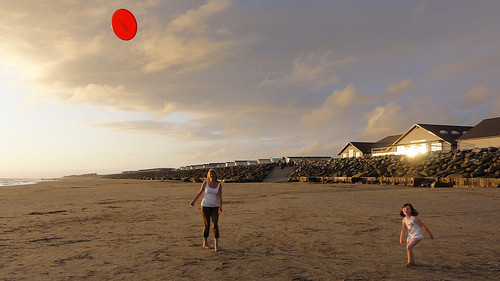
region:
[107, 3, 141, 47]
red plastic frisbee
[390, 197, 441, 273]
little girl wearing white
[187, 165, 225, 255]
woman in a white tank top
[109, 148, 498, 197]
barrier of large grey stones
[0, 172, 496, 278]
light brown sandy beach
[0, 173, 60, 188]
small section of shore line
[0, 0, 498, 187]
cloudy white and blue sky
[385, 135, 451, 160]
yellow sun reflecting off windows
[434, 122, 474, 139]
three sky light windows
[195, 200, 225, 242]
brown capri pants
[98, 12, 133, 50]
red Frisbee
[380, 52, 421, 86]
white clouds in blue sky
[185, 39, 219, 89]
white clouds in blue sky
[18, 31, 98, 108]
white clouds in blue sky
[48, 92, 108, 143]
white clouds in blue sky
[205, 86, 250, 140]
white clouds in blue sky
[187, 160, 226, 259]
lady standing in the sand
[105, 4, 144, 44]
red frisbee in the sky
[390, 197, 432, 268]
girl standing in the sand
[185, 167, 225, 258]
lady wearing a white tank top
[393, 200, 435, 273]
girl wearing a white tank top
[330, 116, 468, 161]
house behind a rock slope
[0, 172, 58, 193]
a small slice of the ocean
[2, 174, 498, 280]
beach is covered in sand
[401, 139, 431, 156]
light reflecting off the window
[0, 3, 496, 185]
sky is blue with clouds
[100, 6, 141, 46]
red Frisbee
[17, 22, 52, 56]
white clouds in blue sky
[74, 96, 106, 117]
white clouds in blue sky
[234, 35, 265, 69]
white clouds in blue sky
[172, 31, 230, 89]
white clouds in blue sky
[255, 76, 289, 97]
white clouds in blue sky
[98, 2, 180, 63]
Frisbee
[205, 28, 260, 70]
white clouds in blue sky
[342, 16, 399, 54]
white clouds in blue sky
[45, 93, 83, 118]
white clouds in blue sky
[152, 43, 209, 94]
white clouds in blue sky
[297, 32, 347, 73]
white clouds in blue sky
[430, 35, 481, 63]
white clouds in blue sky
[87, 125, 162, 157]
white clouds in blue sky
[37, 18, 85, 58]
white clouds in blue sky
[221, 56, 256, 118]
white clouds in blue sky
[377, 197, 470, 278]
person on the beach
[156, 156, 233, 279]
a person on the beach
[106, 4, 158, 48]
an orange frisbee in the air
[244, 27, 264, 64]
a white fluffy cloud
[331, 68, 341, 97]
a white fluffy cloud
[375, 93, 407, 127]
a white fluffy cloud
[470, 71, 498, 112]
a white fluffy cloud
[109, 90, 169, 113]
a white fluffy cloud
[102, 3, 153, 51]
frisbee in the air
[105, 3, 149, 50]
the frisbee is red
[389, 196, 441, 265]
girl on the beach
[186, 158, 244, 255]
woman on the beach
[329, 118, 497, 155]
house in the background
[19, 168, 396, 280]
tracks on the beach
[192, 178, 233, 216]
woman wearing a white tank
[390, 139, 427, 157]
glare on the windows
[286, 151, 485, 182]
rocks on the side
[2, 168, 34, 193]
water in the distance